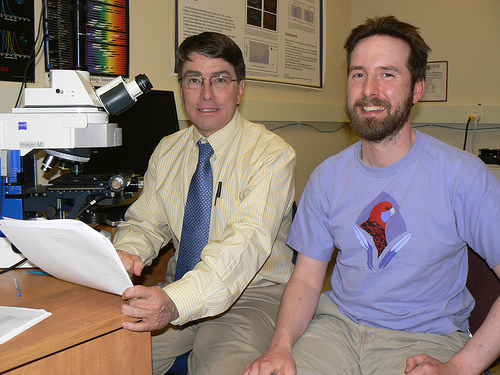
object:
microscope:
[0, 67, 154, 269]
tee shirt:
[283, 126, 498, 334]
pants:
[279, 291, 473, 375]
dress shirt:
[110, 107, 296, 326]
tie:
[173, 138, 216, 283]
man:
[240, 14, 499, 374]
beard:
[345, 98, 411, 142]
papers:
[0, 304, 51, 349]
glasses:
[182, 74, 244, 90]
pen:
[13, 276, 23, 297]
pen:
[213, 181, 223, 205]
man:
[110, 30, 297, 375]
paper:
[0, 214, 137, 302]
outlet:
[464, 183, 472, 191]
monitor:
[87, 85, 183, 193]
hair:
[342, 14, 434, 82]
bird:
[358, 200, 397, 257]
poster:
[42, 0, 132, 81]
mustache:
[353, 96, 392, 109]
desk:
[0, 219, 195, 373]